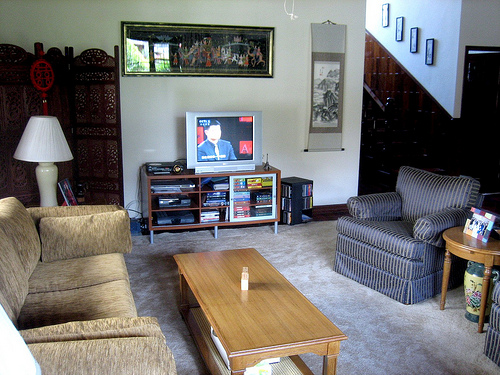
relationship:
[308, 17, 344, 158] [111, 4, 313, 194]
art on wall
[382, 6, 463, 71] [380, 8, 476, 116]
pictures on wall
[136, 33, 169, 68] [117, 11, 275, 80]
windows reflecting in art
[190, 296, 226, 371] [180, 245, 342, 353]
shelf on table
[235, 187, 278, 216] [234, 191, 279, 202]
books on shelf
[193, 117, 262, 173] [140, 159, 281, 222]
tv on stand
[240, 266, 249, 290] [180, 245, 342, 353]
bottle on table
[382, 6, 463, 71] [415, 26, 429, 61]
pictures in frames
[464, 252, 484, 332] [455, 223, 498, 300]
vase under table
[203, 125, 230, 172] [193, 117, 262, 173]
man on tv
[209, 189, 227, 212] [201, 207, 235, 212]
tapes on shelf